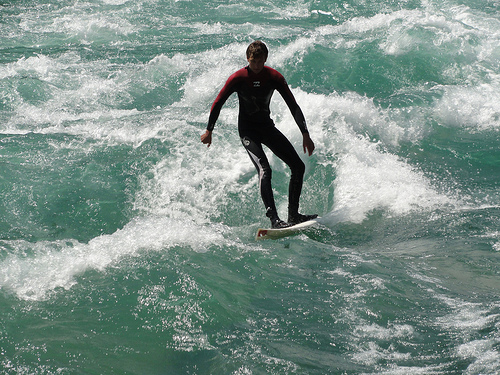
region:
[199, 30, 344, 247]
man riding a surfboard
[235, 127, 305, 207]
wetsuit pants with white design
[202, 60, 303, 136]
red wetsuit top with long sleeves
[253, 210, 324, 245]
white surfboard under feet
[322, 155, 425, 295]
rough water of ocean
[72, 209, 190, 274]
white cap on wave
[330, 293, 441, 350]
white sea foam on water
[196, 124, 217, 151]
bare hand of surfer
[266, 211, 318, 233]
wetsuit booties on feet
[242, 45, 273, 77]
face of surfer looking downward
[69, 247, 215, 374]
the water is green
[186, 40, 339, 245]
the man is surfing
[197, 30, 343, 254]
the man is standing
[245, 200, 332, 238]
the board is white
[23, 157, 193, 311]
the waves are white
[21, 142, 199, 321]
the water is rough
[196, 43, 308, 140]
the shirt is red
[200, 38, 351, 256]
the surfer is a man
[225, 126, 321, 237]
the pants are black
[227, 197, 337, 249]
the board is floating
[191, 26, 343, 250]
Surfer in the ocean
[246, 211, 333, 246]
Surfer is white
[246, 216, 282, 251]
Tip of surfboard is red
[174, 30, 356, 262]
Surfboard wears a red and black suit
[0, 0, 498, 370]
Water is choppy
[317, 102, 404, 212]
Wave is white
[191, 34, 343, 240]
Top of the suit is read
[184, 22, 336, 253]
Low part of the suit is black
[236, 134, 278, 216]
White stripe on right of suite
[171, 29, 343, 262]
Person has arms extended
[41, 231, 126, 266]
This is white foam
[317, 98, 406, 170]
This is ocean spray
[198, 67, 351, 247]
This is a wetsuit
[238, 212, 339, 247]
This is a white surfboard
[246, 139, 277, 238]
This is a white stripe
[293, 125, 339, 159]
This is a left hand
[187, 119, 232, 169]
This is the right hand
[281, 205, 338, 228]
This is the left food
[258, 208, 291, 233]
This is the right food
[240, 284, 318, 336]
This is the water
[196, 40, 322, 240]
Man wearing a black, red, and white wet suit.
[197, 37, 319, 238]
Surfer in a wet suit.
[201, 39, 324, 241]
Man surfing on a white surfboard.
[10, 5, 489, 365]
Man surfing on the beach.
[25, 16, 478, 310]
Surfer on a surfboard surfing on white waves.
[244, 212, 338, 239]
White and red surfboard.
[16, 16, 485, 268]
Man surfing on powerful waves.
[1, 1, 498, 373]
Surfer surfing on blue ocean water.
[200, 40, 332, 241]
Surfer balanced on a white surfboard.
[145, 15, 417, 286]
Man standing on surfboard surfing.